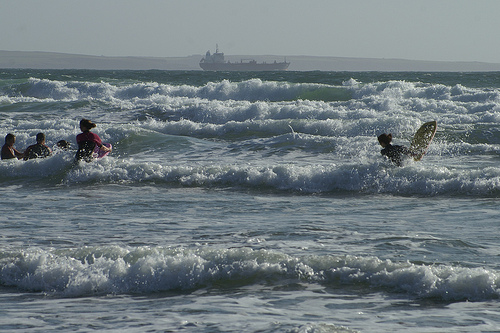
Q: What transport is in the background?
A: Cargo ship.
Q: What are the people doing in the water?
A: Surfing.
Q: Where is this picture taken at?
A: The beach.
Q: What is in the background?
A: Boat.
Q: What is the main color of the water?
A: Blue.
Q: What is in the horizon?
A: Mountains.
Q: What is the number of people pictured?
A: 5.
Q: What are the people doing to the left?
A: Playing in the waves.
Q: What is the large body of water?
A: Ocean.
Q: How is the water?
A: Choppy.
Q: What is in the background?
A: Ship.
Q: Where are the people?
A: Ocean.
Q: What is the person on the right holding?
A: Surfboard.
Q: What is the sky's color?
A: Gray.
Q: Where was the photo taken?
A: Beach.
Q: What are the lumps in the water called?
A: Waves.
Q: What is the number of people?
A: 4.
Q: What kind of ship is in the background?
A: Freighter.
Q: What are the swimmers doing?
A: Surfing.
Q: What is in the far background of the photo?
A: Land.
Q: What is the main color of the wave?
A: White.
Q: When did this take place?
A: During the day.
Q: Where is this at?
A: Beach.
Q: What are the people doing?
A: Playing in the water.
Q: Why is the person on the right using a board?
A: Surfing.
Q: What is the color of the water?
A: Blue.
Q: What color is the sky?
A: Blue.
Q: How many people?
A: Four.